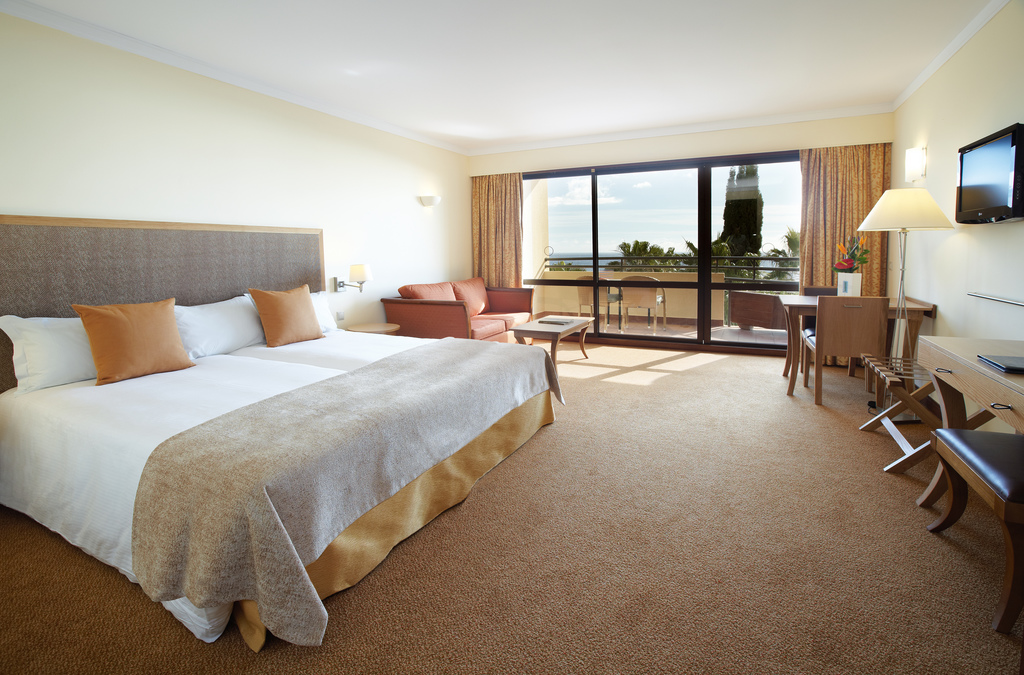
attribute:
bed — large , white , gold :
[26, 295, 557, 591]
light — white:
[315, 252, 377, 297]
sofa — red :
[373, 273, 541, 338]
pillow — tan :
[79, 288, 197, 396]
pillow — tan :
[246, 273, 327, 351]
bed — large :
[0, 216, 571, 647]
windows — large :
[502, 153, 810, 350]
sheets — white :
[36, 251, 637, 662]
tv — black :
[932, 123, 1024, 221]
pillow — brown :
[60, 293, 231, 398]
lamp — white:
[848, 184, 951, 318]